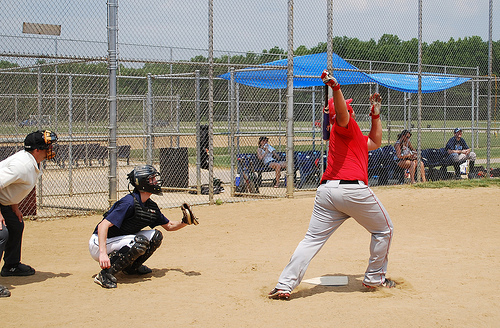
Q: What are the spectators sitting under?
A: A blue tarp.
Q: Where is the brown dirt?
A: On a baseball field.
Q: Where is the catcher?
A: Behind the pitcher.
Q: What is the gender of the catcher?
A: Female.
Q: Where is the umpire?
A: Behind the catcher.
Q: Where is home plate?
A: Under the pitcher.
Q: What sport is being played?
A: Baseball.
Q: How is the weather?
A: Sunny.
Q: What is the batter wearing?
A: A red shirt and grey pants.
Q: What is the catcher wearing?
A: A blue shirt and white pants.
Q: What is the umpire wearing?
A: A beige shirt and black pants.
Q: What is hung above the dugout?
A: A blue tarp.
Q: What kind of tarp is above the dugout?
A: A plastic tarp.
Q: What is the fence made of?
A: Metal.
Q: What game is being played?
A: Baseball.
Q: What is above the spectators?
A: Tarp.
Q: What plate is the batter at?
A: Home.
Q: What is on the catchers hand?
A: Glove.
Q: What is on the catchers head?
A: Helmet.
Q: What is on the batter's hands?
A: Gloves.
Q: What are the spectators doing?
A: Sitting.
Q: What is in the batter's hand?
A: Bat.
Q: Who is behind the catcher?
A: Umpire.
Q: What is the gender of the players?
A: Male.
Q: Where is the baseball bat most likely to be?
A: In the air.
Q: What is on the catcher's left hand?
A: A catcher's mitt.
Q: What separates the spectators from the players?
A: A fence.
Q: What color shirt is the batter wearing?
A: Red.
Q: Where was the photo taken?
A: Baseball Field.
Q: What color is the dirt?
A: Tan.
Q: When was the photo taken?
A: Daytime.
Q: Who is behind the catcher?
A: Umpire.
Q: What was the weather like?
A: Sunny.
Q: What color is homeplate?
A: White.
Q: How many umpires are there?
A: One.